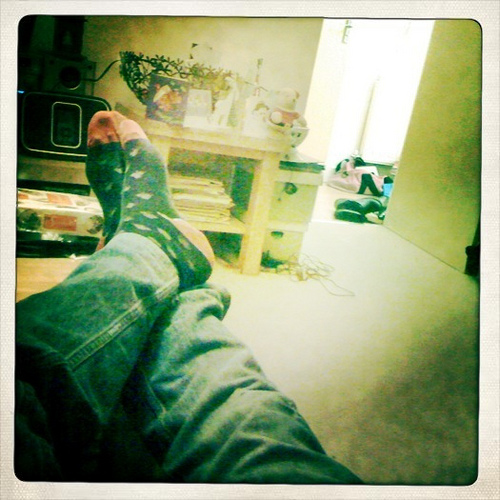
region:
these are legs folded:
[45, 110, 206, 340]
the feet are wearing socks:
[71, 110, 198, 255]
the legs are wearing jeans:
[47, 295, 244, 488]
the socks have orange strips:
[92, 116, 144, 141]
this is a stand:
[220, 145, 272, 236]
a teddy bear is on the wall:
[269, 93, 299, 131]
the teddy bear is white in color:
[270, 92, 304, 134]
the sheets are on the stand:
[183, 175, 225, 218]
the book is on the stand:
[157, 88, 189, 111]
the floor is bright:
[277, 293, 344, 348]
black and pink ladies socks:
[80, 107, 220, 289]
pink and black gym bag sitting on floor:
[331, 144, 399, 201]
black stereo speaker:
[33, 43, 105, 163]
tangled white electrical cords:
[270, 239, 366, 317]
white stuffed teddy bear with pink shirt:
[265, 80, 311, 137]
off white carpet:
[374, 246, 461, 420]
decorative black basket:
[117, 43, 239, 95]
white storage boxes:
[235, 151, 321, 268]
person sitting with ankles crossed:
[0, 206, 391, 497]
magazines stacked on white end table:
[137, 105, 290, 272]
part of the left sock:
[137, 197, 202, 264]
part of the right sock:
[84, 141, 114, 193]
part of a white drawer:
[278, 182, 300, 256]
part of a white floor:
[372, 239, 435, 361]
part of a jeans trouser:
[187, 353, 276, 440]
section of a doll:
[268, 90, 303, 122]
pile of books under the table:
[184, 168, 229, 220]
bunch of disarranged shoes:
[331, 150, 383, 224]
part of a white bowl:
[292, 122, 304, 147]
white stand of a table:
[244, 213, 261, 269]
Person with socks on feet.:
[79, 106, 251, 320]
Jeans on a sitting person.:
[43, 250, 428, 495]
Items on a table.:
[118, 48, 330, 245]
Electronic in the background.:
[35, 38, 111, 168]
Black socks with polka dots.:
[55, 107, 260, 346]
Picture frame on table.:
[137, 62, 319, 172]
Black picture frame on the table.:
[125, 38, 304, 139]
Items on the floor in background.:
[328, 130, 438, 300]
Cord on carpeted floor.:
[264, 236, 389, 336]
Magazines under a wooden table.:
[148, 157, 276, 266]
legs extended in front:
[31, 100, 366, 465]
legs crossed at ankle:
[75, 95, 285, 345]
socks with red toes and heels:
[75, 91, 230, 271]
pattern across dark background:
[80, 126, 235, 278]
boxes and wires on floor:
[260, 146, 365, 326]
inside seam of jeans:
[60, 231, 201, 386]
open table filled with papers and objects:
[111, 75, 296, 275]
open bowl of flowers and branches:
[110, 40, 235, 110]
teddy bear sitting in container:
[250, 80, 315, 160]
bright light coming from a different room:
[305, 40, 423, 241]